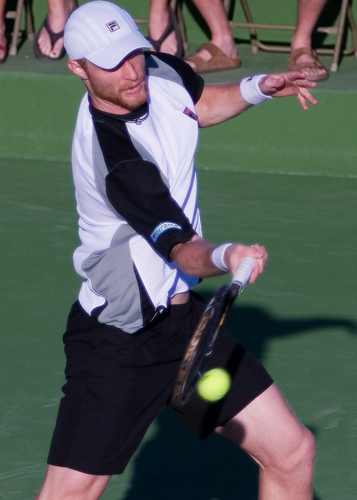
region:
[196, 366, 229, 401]
the ball in mid air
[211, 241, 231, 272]
the wristband on the man's wrist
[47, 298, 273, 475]
the shorts on the man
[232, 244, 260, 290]
the handle of the tennis racquet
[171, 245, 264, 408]
the tennis racquet the man is holding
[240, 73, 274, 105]
the wristband on the man's wrist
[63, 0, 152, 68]
the hat on the man's head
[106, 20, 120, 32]
the logo on the man's hat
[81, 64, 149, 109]
the facial hair on the man's face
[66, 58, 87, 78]
the ear on the man's head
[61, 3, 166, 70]
The man is wearing a hat.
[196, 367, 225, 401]
The ball is yellow.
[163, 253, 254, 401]
The racket is black.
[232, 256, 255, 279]
The handle is white.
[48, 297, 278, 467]
The man's shorts are black.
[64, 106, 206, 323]
The man's shirt is white.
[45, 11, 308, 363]
He is swinging the racket.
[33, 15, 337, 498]
He is playing tennis.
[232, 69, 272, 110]
The sweat band is white.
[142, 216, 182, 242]
The label is on his shirt.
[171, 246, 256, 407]
a tennis ball in front of the racquet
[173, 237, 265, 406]
a tennis racquet in the man's hand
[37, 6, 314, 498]
a man playing tennis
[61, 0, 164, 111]
a cap on the man's head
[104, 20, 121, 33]
a logo for the company Fila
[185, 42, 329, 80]
a person wearing brown slippers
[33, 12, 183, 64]
a person wearing black flip flops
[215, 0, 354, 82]
the bottom of a tan colored chair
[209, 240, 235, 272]
a white wrist band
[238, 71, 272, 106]
a white wrist band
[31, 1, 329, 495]
A man playing tennis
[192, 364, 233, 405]
A round tennis ball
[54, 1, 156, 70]
White hat on man's head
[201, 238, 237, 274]
A white arm band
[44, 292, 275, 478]
A pair of black shorts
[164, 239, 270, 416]
Tennis racket in a hand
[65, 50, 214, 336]
White, black and gray shirt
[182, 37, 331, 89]
A pair of brown sandals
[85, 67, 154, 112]
Facial hair on man's face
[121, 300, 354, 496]
Man's shadow on the court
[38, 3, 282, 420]
a man with a racket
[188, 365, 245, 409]
a green ball in front of racket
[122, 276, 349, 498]
shadow of man on ground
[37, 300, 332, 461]
black shorts on man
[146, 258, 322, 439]
a white and black racket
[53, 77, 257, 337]
a white black and gray shirt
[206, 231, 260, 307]
white wristband on wrist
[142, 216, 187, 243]
a white strip with manufacture name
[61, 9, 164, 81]
a white hat on head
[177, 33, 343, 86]
brown sandals on feet